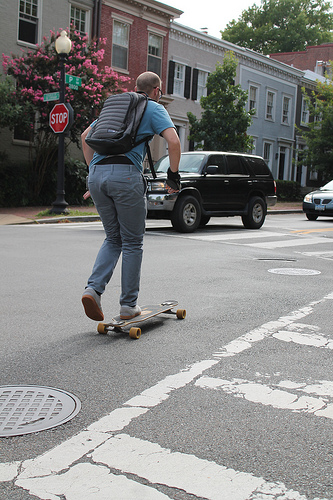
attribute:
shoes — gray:
[80, 288, 142, 326]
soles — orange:
[80, 293, 103, 322]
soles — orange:
[119, 313, 138, 318]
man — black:
[76, 69, 185, 321]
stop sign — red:
[48, 103, 72, 132]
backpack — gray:
[83, 80, 149, 144]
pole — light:
[54, 50, 73, 209]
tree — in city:
[0, 17, 134, 235]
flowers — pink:
[4, 19, 131, 126]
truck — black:
[150, 146, 276, 232]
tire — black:
[242, 195, 265, 228]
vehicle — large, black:
[140, 147, 277, 231]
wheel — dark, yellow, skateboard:
[126, 326, 144, 340]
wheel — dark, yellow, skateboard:
[93, 319, 108, 335]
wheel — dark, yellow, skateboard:
[175, 305, 187, 320]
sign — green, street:
[60, 71, 87, 94]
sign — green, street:
[41, 89, 61, 104]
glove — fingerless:
[164, 165, 185, 189]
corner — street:
[6, 207, 92, 243]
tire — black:
[174, 191, 201, 233]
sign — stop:
[44, 102, 72, 130]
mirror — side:
[204, 161, 220, 177]